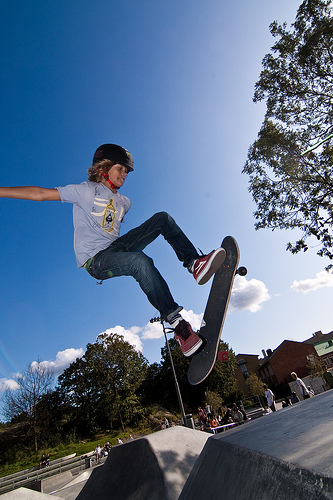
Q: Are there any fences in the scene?
A: No, there are no fences.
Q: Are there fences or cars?
A: No, there are no fences or cars.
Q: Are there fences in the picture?
A: No, there are no fences.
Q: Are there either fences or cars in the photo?
A: No, there are no fences or cars.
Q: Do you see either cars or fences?
A: No, there are no fences or cars.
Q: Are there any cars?
A: No, there are no cars.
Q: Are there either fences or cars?
A: No, there are no cars or fences.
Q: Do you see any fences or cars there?
A: No, there are no cars or fences.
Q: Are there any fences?
A: No, there are no fences.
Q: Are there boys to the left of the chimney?
A: Yes, there is a boy to the left of the chimney.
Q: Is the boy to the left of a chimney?
A: Yes, the boy is to the left of a chimney.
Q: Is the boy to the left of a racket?
A: No, the boy is to the left of a chimney.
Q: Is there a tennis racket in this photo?
A: No, there are no rackets.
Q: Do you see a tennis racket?
A: No, there are no rackets.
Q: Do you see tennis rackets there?
A: No, there are no tennis rackets.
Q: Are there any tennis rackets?
A: No, there are no tennis rackets.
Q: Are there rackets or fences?
A: No, there are no rackets or fences.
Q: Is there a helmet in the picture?
A: Yes, there is a helmet.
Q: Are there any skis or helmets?
A: Yes, there is a helmet.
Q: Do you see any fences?
A: No, there are no fences.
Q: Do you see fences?
A: No, there are no fences.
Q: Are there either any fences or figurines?
A: No, there are no fences or figurines.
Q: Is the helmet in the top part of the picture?
A: Yes, the helmet is in the top of the image.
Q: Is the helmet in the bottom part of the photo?
A: No, the helmet is in the top of the image.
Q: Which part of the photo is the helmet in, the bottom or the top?
A: The helmet is in the top of the image.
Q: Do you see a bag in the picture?
A: No, there are no bags.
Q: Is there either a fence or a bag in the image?
A: No, there are no bags or fences.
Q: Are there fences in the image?
A: No, there are no fences.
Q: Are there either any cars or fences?
A: No, there are no fences or cars.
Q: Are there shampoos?
A: No, there are no shampoos.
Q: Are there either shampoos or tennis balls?
A: No, there are no shampoos or tennis balls.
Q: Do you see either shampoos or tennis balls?
A: No, there are no shampoos or tennis balls.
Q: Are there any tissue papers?
A: No, there are no tissue papers.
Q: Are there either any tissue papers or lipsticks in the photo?
A: No, there are no tissue papers or lipsticks.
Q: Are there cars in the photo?
A: No, there are no cars.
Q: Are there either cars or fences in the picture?
A: No, there are no cars or fences.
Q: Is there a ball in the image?
A: No, there are no balls.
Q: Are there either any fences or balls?
A: No, there are no balls or fences.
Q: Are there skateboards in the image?
A: Yes, there is a skateboard.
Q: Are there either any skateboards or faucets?
A: Yes, there is a skateboard.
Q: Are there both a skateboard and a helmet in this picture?
A: Yes, there are both a skateboard and a helmet.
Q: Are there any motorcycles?
A: No, there are no motorcycles.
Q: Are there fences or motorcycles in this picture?
A: No, there are no motorcycles or fences.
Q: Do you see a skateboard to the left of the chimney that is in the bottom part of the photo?
A: Yes, there is a skateboard to the left of the chimney.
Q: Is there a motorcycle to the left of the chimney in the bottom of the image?
A: No, there is a skateboard to the left of the chimney.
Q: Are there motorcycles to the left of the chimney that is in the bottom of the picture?
A: No, there is a skateboard to the left of the chimney.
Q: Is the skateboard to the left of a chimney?
A: Yes, the skateboard is to the left of a chimney.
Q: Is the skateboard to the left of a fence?
A: No, the skateboard is to the left of a chimney.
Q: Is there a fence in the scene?
A: No, there are no fences.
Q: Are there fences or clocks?
A: No, there are no fences or clocks.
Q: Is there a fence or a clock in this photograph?
A: No, there are no fences or clocks.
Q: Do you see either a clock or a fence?
A: No, there are no fences or clocks.